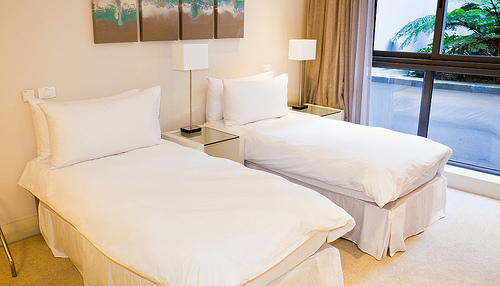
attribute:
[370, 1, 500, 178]
windows — partitioned, open, large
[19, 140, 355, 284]
linen — white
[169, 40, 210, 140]
lamp — modern style, tall, square shaped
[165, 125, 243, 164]
night stand — white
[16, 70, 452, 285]
two beds — decorated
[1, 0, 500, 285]
hotel room — a hotel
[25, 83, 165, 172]
pillows — large, white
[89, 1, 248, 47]
painting — separated, brown, decorative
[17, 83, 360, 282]
bed — white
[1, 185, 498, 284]
ground — carpeted, white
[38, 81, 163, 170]
pillow — white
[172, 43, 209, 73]
shade — white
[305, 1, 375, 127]
curtains — long, beige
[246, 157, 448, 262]
bed skirt — white